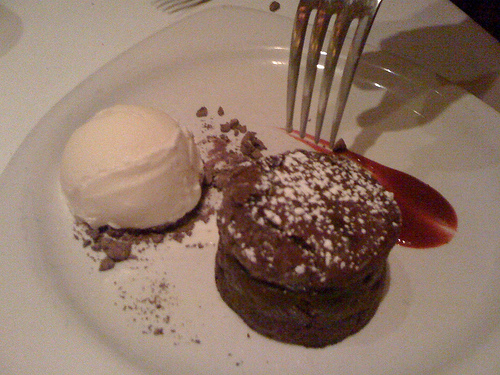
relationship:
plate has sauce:
[0, 7, 499, 374] [288, 125, 457, 249]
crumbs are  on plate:
[185, 93, 265, 163] [0, 7, 499, 374]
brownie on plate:
[197, 152, 405, 343] [0, 7, 499, 374]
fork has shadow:
[284, 0, 379, 149] [341, 21, 491, 152]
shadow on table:
[390, 26, 448, 87] [81, 12, 117, 41]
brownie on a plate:
[210, 146, 405, 353] [0, 7, 499, 374]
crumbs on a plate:
[122, 275, 182, 340] [82, 36, 499, 332]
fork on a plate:
[254, 3, 396, 144] [0, 7, 499, 374]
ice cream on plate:
[57, 100, 202, 231] [0, 7, 499, 374]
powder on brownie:
[217, 150, 399, 285] [210, 146, 405, 353]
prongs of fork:
[331, 11, 377, 143] [280, 2, 383, 148]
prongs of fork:
[312, 12, 351, 142] [280, 2, 383, 148]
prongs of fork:
[301, 10, 329, 139] [280, 2, 383, 148]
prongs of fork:
[287, 9, 309, 132] [280, 2, 383, 148]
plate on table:
[0, 7, 499, 374] [2, 2, 133, 147]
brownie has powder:
[210, 146, 405, 353] [263, 149, 388, 240]